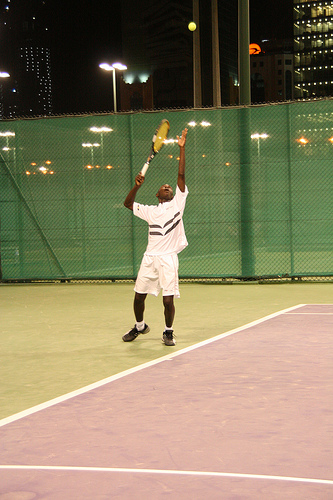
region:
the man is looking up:
[125, 146, 197, 314]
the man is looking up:
[103, 87, 218, 310]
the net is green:
[20, 139, 98, 207]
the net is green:
[182, 111, 269, 199]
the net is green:
[39, 149, 105, 226]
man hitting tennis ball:
[119, 114, 192, 348]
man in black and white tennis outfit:
[135, 189, 187, 304]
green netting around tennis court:
[6, 102, 331, 286]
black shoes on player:
[117, 311, 181, 348]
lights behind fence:
[96, 49, 125, 97]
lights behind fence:
[89, 124, 109, 162]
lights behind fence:
[250, 127, 270, 168]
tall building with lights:
[278, 2, 331, 167]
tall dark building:
[5, 0, 59, 133]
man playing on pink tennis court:
[0, 298, 331, 498]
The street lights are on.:
[100, 55, 124, 78]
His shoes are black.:
[113, 317, 186, 352]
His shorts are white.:
[129, 249, 177, 289]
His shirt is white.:
[132, 185, 200, 261]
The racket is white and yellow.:
[133, 116, 172, 184]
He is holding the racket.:
[114, 120, 192, 352]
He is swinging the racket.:
[120, 122, 187, 345]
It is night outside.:
[3, 7, 332, 105]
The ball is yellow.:
[182, 18, 196, 34]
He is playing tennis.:
[94, 9, 209, 356]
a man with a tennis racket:
[90, 106, 225, 359]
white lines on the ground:
[30, 291, 332, 498]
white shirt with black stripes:
[130, 197, 201, 252]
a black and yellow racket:
[133, 120, 178, 188]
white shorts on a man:
[123, 246, 211, 319]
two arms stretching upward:
[105, 109, 214, 233]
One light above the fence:
[87, 48, 134, 131]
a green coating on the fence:
[13, 113, 328, 289]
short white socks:
[133, 320, 176, 334]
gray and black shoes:
[121, 329, 178, 353]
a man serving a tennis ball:
[118, 114, 195, 349]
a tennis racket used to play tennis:
[138, 117, 173, 179]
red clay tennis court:
[5, 304, 330, 496]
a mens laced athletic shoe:
[120, 324, 153, 344]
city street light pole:
[97, 60, 133, 111]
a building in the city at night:
[291, 0, 331, 103]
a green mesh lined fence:
[2, 97, 330, 285]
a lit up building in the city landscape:
[13, 34, 58, 117]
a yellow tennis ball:
[181, 15, 205, 37]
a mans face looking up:
[154, 179, 177, 206]